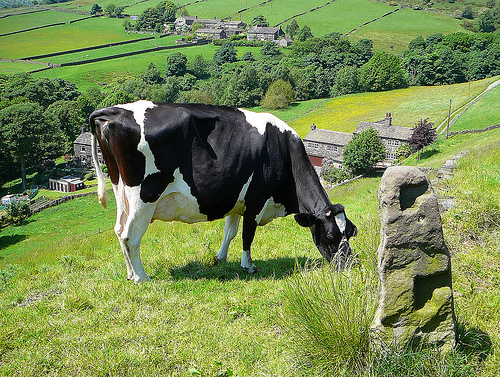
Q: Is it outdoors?
A: Yes, it is outdoors.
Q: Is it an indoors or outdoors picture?
A: It is outdoors.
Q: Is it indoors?
A: No, it is outdoors.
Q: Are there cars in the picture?
A: No, there are no cars.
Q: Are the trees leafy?
A: Yes, the trees are leafy.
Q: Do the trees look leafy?
A: Yes, the trees are leafy.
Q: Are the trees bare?
A: No, the trees are leafy.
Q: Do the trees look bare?
A: No, the trees are leafy.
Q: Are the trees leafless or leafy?
A: The trees are leafy.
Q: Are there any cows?
A: Yes, there is a cow.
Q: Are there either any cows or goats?
A: Yes, there is a cow.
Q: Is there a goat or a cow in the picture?
A: Yes, there is a cow.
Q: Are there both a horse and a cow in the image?
A: No, there is a cow but no horses.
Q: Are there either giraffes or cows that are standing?
A: Yes, the cow is standing.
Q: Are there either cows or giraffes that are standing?
A: Yes, the cow is standing.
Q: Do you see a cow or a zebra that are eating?
A: Yes, the cow is eating.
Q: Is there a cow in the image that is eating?
A: Yes, there is a cow that is eating.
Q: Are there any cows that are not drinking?
A: Yes, there is a cow that is eating.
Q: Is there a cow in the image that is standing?
A: Yes, there is a cow that is standing.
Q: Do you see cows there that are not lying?
A: Yes, there is a cow that is standing .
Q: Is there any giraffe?
A: No, there are no giraffes.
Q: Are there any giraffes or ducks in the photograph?
A: No, there are no giraffes or ducks.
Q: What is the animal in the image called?
A: The animal is a cow.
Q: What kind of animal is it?
A: The animal is a cow.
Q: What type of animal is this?
A: This is a cow.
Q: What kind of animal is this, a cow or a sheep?
A: This is a cow.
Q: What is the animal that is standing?
A: The animal is a cow.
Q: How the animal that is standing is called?
A: The animal is a cow.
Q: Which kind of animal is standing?
A: The animal is a cow.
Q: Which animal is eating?
A: The animal is a cow.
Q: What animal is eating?
A: The animal is a cow.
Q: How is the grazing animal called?
A: The animal is a cow.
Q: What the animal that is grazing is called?
A: The animal is a cow.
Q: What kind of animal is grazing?
A: The animal is a cow.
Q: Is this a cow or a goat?
A: This is a cow.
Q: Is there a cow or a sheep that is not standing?
A: No, there is a cow but it is standing.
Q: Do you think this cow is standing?
A: Yes, the cow is standing.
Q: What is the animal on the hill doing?
A: The cow is standing.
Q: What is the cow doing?
A: The cow is standing.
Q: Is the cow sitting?
A: No, the cow is standing.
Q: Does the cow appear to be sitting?
A: No, the cow is standing.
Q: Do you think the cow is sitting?
A: No, the cow is standing.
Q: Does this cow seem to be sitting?
A: No, the cow is standing.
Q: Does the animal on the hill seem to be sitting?
A: No, the cow is standing.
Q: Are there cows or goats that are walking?
A: No, there is a cow but it is standing.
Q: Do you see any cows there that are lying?
A: No, there is a cow but it is standing.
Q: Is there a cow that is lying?
A: No, there is a cow but it is standing.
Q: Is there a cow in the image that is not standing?
A: No, there is a cow but it is standing.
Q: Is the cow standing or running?
A: The cow is standing.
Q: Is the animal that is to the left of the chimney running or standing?
A: The cow is standing.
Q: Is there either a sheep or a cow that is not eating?
A: No, there is a cow but it is eating.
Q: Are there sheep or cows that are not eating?
A: No, there is a cow but it is eating.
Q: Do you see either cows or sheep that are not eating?
A: No, there is a cow but it is eating.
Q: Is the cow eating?
A: Yes, the cow is eating.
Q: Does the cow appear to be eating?
A: Yes, the cow is eating.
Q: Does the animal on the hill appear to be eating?
A: Yes, the cow is eating.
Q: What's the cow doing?
A: The cow is eating.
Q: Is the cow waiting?
A: No, the cow is eating.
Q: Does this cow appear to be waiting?
A: No, the cow is eating.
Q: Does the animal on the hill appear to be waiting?
A: No, the cow is eating.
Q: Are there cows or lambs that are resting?
A: No, there is a cow but it is eating.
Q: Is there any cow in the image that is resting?
A: No, there is a cow but it is eating.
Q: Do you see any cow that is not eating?
A: No, there is a cow but it is eating.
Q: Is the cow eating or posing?
A: The cow is eating.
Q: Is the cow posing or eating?
A: The cow is eating.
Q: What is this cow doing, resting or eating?
A: The cow is eating.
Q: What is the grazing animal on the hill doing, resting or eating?
A: The cow is eating.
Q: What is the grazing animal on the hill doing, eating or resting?
A: The cow is eating.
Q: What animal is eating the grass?
A: The cow is eating the grass.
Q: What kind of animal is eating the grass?
A: The animal is a cow.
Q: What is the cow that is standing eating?
A: The cow is eating grass.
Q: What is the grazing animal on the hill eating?
A: The cow is eating grass.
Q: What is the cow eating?
A: The cow is eating grass.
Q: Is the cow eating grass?
A: Yes, the cow is eating grass.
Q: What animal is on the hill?
A: The cow is on the hill.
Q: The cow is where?
A: The cow is on the hill.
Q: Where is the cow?
A: The cow is on the hill.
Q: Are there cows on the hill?
A: Yes, there is a cow on the hill.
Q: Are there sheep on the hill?
A: No, there is a cow on the hill.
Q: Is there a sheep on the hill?
A: No, there is a cow on the hill.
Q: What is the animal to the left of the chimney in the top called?
A: The animal is a cow.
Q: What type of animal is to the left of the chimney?
A: The animal is a cow.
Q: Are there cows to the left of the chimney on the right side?
A: Yes, there is a cow to the left of the chimney.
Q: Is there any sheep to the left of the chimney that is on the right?
A: No, there is a cow to the left of the chimney.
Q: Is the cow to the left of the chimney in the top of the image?
A: Yes, the cow is to the left of the chimney.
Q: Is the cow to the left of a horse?
A: No, the cow is to the left of the chimney.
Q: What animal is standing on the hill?
A: The cow is standing on the hill.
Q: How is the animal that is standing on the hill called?
A: The animal is a cow.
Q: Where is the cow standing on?
A: The cow is standing on the hill.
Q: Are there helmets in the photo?
A: No, there are no helmets.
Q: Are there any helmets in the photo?
A: No, there are no helmets.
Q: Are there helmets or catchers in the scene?
A: No, there are no helmets or catchers.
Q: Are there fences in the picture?
A: Yes, there is a fence.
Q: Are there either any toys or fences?
A: Yes, there is a fence.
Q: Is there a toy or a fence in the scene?
A: Yes, there is a fence.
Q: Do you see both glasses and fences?
A: No, there is a fence but no glasses.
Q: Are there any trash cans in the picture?
A: No, there are no trash cans.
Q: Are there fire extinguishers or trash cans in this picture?
A: No, there are no trash cans or fire extinguishers.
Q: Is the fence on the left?
A: Yes, the fence is on the left of the image.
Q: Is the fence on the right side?
A: No, the fence is on the left of the image.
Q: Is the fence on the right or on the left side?
A: The fence is on the left of the image.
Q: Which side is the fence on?
A: The fence is on the left of the image.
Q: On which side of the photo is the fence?
A: The fence is on the left of the image.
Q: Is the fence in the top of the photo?
A: Yes, the fence is in the top of the image.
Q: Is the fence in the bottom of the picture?
A: No, the fence is in the top of the image.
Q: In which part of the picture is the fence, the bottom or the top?
A: The fence is in the top of the image.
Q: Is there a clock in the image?
A: No, there are no clocks.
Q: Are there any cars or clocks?
A: No, there are no clocks or cars.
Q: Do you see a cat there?
A: No, there are no cats.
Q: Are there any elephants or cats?
A: No, there are no cats or elephants.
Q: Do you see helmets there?
A: No, there are no helmets.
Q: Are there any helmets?
A: No, there are no helmets.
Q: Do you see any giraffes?
A: No, there are no giraffes.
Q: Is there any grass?
A: Yes, there is grass.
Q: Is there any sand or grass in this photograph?
A: Yes, there is grass.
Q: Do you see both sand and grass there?
A: No, there is grass but no sand.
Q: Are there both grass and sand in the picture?
A: No, there is grass but no sand.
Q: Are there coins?
A: No, there are no coins.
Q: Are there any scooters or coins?
A: No, there are no coins or scooters.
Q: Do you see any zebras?
A: No, there are no zebras.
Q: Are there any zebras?
A: No, there are no zebras.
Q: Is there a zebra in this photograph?
A: No, there are no zebras.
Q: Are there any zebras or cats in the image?
A: No, there are no zebras or cats.